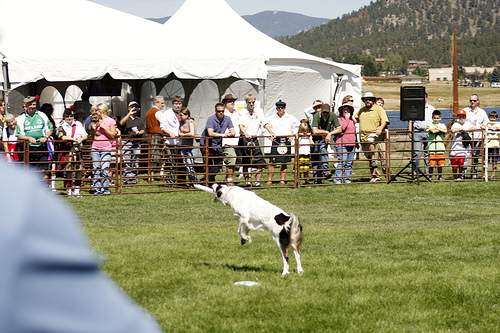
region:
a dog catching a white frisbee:
[190, 179, 317, 276]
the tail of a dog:
[285, 209, 305, 251]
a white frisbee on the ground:
[225, 273, 270, 291]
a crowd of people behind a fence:
[12, 92, 484, 175]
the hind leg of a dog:
[272, 230, 292, 282]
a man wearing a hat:
[354, 87, 392, 181]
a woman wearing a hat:
[333, 102, 360, 186]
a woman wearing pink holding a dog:
[85, 99, 120, 199]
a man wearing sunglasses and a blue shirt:
[200, 102, 240, 188]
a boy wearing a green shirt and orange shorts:
[425, 109, 451, 182]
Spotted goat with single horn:
[191, 170, 314, 282]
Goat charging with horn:
[185, 168, 307, 280]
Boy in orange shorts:
[423, 100, 448, 188]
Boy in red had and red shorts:
[448, 107, 476, 176]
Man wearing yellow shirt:
[353, 88, 389, 181]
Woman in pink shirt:
[86, 95, 124, 197]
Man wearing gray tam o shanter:
[15, 88, 59, 188]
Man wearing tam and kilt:
[263, 96, 300, 188]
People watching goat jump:
[0, 78, 373, 280]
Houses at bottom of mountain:
[336, 0, 499, 84]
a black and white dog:
[171, 170, 355, 285]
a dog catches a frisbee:
[178, 168, 319, 290]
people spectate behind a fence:
[28, 98, 487, 185]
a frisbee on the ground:
[225, 265, 297, 303]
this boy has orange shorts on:
[426, 110, 457, 205]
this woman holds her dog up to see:
[81, 100, 113, 135]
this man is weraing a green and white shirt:
[21, 95, 53, 143]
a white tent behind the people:
[3, 0, 383, 97]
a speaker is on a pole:
[382, 77, 431, 193]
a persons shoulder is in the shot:
[3, 147, 98, 328]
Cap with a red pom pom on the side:
[22, 94, 40, 104]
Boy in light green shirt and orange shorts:
[427, 110, 446, 182]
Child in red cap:
[447, 108, 472, 178]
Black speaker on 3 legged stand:
[389, 84, 434, 185]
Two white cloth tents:
[1, 1, 362, 131]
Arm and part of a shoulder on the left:
[0, 160, 153, 331]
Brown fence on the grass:
[7, 126, 496, 196]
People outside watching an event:
[3, 90, 497, 187]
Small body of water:
[381, 105, 498, 132]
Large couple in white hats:
[337, 90, 387, 184]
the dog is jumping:
[200, 170, 422, 320]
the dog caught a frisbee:
[180, 159, 389, 268]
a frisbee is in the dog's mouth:
[160, 171, 427, 303]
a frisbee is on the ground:
[228, 260, 287, 293]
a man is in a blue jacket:
[25, 184, 57, 276]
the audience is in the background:
[86, 85, 435, 154]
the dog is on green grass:
[167, 168, 285, 282]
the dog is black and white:
[185, 170, 417, 280]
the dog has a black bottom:
[269, 203, 321, 300]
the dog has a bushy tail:
[277, 208, 299, 248]